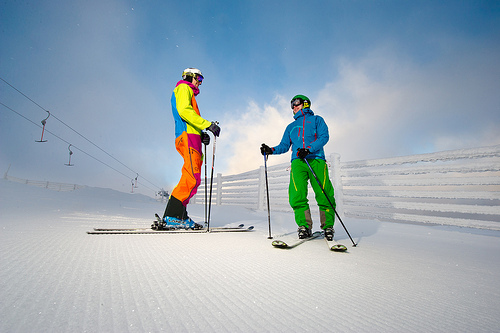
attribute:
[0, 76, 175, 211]
ski lift — empty of people, up high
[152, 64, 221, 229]
person — in bright clothing, tall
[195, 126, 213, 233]
ski pole — used for skiing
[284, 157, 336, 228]
pants — green, orange, lime green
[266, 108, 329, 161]
jacket — blue, yellow, multi-colored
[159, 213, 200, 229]
ski boot — blue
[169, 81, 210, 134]
jacket — multi-colored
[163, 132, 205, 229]
pants — bright orange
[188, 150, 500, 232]
fence — snow covered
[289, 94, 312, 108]
helmet — green, yellow, white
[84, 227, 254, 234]
ski — extra long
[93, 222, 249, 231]
ski — extra long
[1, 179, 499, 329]
hill — groomer marked, lined, sparkly, snowy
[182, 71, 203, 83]
goggles — black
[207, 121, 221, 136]
glove — dark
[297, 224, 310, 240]
binding — black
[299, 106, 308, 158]
zipper — pink